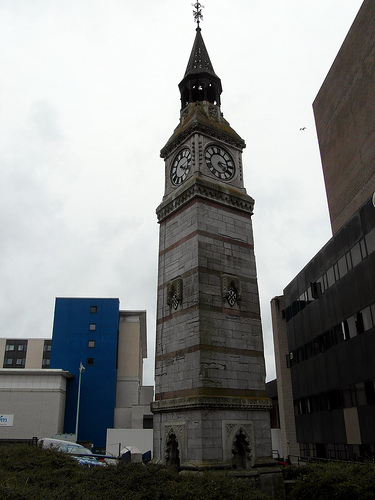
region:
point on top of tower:
[191, 2, 207, 51]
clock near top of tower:
[166, 127, 230, 197]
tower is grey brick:
[161, 194, 249, 386]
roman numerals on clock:
[166, 141, 223, 181]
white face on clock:
[208, 156, 227, 178]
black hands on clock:
[206, 156, 249, 182]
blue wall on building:
[48, 303, 97, 429]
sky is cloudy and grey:
[23, 95, 150, 295]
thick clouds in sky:
[32, 47, 100, 175]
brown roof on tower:
[169, 84, 252, 161]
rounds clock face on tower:
[195, 138, 237, 181]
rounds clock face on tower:
[163, 145, 191, 179]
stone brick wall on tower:
[152, 222, 270, 429]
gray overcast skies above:
[70, 133, 120, 219]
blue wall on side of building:
[47, 293, 128, 449]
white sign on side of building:
[0, 413, 27, 428]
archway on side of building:
[158, 412, 189, 472]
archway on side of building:
[218, 415, 257, 467]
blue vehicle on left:
[18, 423, 97, 484]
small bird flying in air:
[286, 115, 309, 145]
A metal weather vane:
[191, 0, 203, 25]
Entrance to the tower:
[221, 421, 254, 465]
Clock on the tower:
[204, 141, 236, 181]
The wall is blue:
[48, 296, 118, 452]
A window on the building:
[3, 343, 15, 351]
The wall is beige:
[104, 428, 152, 462]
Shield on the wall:
[226, 290, 236, 307]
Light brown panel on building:
[343, 407, 360, 446]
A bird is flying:
[300, 125, 306, 130]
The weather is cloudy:
[0, 0, 365, 402]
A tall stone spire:
[140, 1, 282, 478]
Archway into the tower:
[163, 428, 180, 467]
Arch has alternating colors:
[230, 426, 253, 464]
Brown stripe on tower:
[154, 386, 266, 400]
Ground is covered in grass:
[0, 445, 373, 499]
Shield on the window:
[225, 291, 238, 306]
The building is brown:
[281, 194, 373, 467]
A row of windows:
[286, 231, 373, 319]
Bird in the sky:
[298, 126, 304, 131]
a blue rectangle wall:
[35, 284, 129, 441]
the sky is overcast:
[6, 107, 97, 251]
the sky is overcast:
[65, 149, 134, 258]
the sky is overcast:
[35, 150, 104, 267]